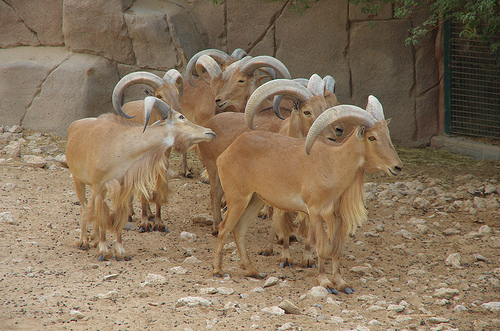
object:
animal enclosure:
[1, 0, 498, 331]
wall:
[0, 0, 444, 151]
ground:
[0, 124, 500, 330]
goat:
[211, 95, 403, 294]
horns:
[304, 95, 385, 155]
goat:
[66, 96, 216, 263]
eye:
[179, 113, 185, 121]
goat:
[212, 48, 318, 119]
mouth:
[215, 101, 227, 108]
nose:
[394, 165, 401, 173]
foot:
[333, 282, 356, 294]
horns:
[113, 69, 187, 119]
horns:
[246, 73, 325, 131]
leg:
[214, 185, 249, 269]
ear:
[357, 125, 366, 141]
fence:
[443, 0, 499, 149]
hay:
[378, 145, 500, 180]